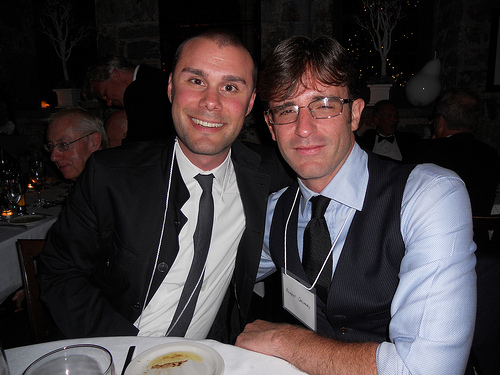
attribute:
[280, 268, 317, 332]
tag — lamenated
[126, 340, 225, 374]
plate — dirty, white, empty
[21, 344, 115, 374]
glass — wine glass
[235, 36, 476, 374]
man — squinting, old, trying, older, happy, smiling, finished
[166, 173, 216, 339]
tie — black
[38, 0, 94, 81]
tree — white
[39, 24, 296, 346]
man — smiling, happy, finished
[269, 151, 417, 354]
vest — gray, black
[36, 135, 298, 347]
suit — black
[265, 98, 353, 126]
glasses — silver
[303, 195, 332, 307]
tie — black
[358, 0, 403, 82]
tree — white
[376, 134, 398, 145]
bow tie — black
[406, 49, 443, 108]
sculpture — pear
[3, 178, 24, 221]
glass — wine glass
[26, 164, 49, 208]
glass — wine glass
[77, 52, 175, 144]
man — meeting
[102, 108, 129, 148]
man — meeting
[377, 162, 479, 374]
shirt — blue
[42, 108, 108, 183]
man — balding